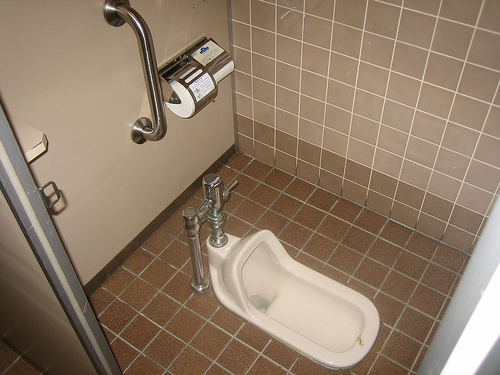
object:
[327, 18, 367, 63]
tile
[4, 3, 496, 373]
restroom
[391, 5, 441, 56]
tile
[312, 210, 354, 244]
tile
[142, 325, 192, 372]
tile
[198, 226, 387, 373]
urinal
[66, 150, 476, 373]
floor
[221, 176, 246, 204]
handle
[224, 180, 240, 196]
flashing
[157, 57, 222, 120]
dispenser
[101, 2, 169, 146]
handicap bar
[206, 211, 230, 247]
water pipe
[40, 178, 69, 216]
latch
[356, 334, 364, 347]
stain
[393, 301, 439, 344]
tile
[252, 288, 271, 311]
hole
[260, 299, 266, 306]
water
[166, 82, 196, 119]
toilet paper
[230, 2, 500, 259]
wall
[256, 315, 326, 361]
rim